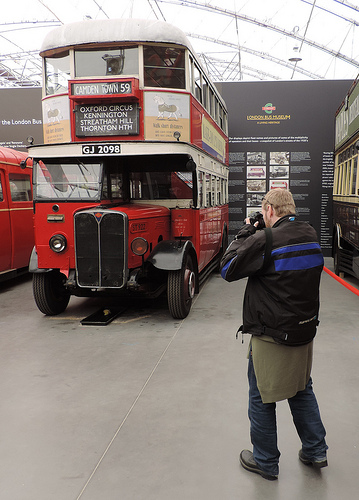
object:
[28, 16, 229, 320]
bus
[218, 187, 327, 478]
man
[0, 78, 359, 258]
wall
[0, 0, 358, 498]
bus museum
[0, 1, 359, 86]
ceiling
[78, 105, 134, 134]
route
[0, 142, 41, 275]
part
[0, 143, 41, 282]
vehicle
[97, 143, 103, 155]
number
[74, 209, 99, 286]
grill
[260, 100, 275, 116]
logo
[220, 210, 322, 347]
coat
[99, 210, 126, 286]
radiator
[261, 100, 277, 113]
sign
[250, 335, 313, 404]
sweater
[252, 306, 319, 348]
waist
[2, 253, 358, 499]
floor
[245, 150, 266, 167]
pictures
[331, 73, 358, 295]
bus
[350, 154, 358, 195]
windows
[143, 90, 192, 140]
sign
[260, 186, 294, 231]
head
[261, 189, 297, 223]
hair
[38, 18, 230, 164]
second story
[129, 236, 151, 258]
headlight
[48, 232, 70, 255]
headlight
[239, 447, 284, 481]
left shoe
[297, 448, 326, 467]
right shoe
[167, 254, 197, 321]
tire